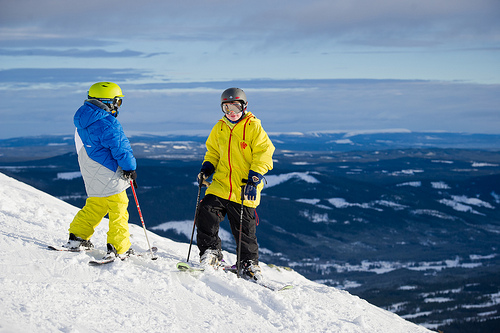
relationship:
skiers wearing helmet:
[46, 79, 158, 265] [89, 82, 126, 102]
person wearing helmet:
[200, 89, 260, 277] [219, 90, 250, 110]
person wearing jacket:
[200, 89, 260, 277] [204, 112, 274, 200]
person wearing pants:
[200, 89, 260, 277] [197, 189, 260, 267]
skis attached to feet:
[58, 245, 169, 269] [68, 232, 134, 258]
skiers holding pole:
[46, 79, 158, 265] [122, 168, 164, 259]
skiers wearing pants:
[46, 79, 158, 265] [76, 191, 134, 252]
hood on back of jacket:
[74, 100, 114, 126] [74, 99, 132, 187]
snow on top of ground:
[8, 178, 420, 333] [5, 181, 426, 332]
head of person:
[216, 82, 252, 124] [200, 89, 260, 277]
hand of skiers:
[115, 162, 136, 180] [46, 79, 158, 265]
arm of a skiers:
[107, 119, 138, 176] [46, 79, 158, 265]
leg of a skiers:
[110, 193, 130, 255] [46, 79, 158, 265]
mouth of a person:
[229, 114, 239, 120] [200, 89, 260, 277]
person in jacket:
[200, 89, 260, 277] [204, 112, 274, 200]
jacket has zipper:
[204, 112, 274, 200] [227, 126, 233, 201]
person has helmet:
[200, 89, 260, 277] [219, 90, 250, 110]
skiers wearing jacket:
[46, 79, 158, 265] [74, 99, 132, 187]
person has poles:
[200, 89, 260, 277] [185, 174, 249, 269]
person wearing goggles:
[200, 89, 260, 277] [221, 99, 244, 115]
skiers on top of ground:
[68, 79, 272, 269] [5, 181, 426, 332]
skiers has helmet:
[46, 79, 158, 265] [89, 82, 126, 102]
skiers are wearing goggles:
[68, 79, 272, 269] [221, 99, 244, 115]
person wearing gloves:
[200, 89, 260, 277] [200, 163, 263, 194]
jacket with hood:
[74, 99, 132, 187] [74, 100, 114, 126]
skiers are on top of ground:
[68, 79, 272, 269] [5, 181, 426, 332]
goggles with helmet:
[221, 99, 244, 115] [219, 90, 250, 110]